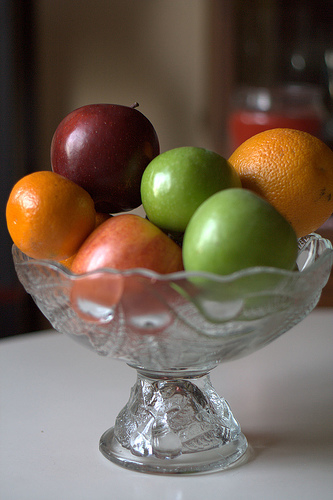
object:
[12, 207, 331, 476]
dish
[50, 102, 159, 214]
apple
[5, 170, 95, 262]
tangerine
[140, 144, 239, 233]
apple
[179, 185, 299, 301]
apple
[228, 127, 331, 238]
orange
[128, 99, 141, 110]
stem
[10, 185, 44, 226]
reflection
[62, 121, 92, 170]
reflection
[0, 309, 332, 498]
table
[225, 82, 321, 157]
candle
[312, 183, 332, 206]
spot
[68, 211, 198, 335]
apple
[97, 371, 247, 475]
bottom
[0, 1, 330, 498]
restaurant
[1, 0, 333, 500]
background